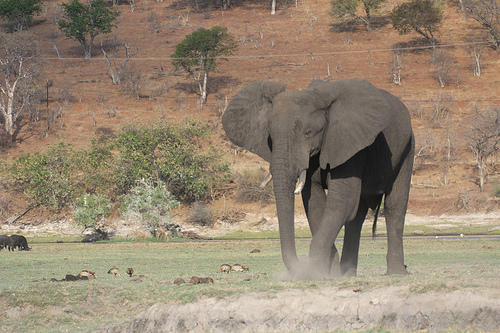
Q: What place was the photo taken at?
A: It was taken at the field.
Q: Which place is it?
A: It is a field.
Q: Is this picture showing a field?
A: Yes, it is showing a field.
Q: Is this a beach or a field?
A: It is a field.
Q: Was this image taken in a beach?
A: No, the picture was taken in a field.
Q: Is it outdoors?
A: Yes, it is outdoors.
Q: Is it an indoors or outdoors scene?
A: It is outdoors.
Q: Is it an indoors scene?
A: No, it is outdoors.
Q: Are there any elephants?
A: Yes, there is an elephant.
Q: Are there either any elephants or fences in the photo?
A: Yes, there is an elephant.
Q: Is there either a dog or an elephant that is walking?
A: Yes, the elephant is walking.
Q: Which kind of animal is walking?
A: The animal is an elephant.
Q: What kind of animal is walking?
A: The animal is an elephant.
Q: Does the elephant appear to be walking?
A: Yes, the elephant is walking.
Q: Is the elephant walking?
A: Yes, the elephant is walking.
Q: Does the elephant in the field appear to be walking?
A: Yes, the elephant is walking.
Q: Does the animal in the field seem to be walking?
A: Yes, the elephant is walking.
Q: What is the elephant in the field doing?
A: The elephant is walking.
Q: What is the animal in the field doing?
A: The elephant is walking.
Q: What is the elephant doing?
A: The elephant is walking.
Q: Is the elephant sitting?
A: No, the elephant is walking.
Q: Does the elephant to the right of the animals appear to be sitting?
A: No, the elephant is walking.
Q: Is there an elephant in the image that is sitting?
A: No, there is an elephant but it is walking.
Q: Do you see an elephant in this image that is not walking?
A: No, there is an elephant but it is walking.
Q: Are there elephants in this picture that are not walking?
A: No, there is an elephant but it is walking.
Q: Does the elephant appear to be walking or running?
A: The elephant is walking.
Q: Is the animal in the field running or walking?
A: The elephant is walking.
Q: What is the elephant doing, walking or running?
A: The elephant is walking.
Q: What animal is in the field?
A: The elephant is in the field.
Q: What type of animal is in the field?
A: The animal is an elephant.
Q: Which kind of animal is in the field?
A: The animal is an elephant.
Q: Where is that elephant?
A: The elephant is in the field.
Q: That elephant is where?
A: The elephant is in the field.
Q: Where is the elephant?
A: The elephant is in the field.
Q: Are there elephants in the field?
A: Yes, there is an elephant in the field.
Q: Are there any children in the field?
A: No, there is an elephant in the field.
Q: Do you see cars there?
A: No, there are no cars.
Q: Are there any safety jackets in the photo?
A: No, there are no safety jackets.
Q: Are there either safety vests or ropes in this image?
A: No, there are no safety vests or ropes.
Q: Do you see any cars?
A: No, there are no cars.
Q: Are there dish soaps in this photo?
A: No, there are no dish soaps.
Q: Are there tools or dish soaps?
A: No, there are no dish soaps or tools.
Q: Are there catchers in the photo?
A: No, there are no catchers.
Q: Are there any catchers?
A: No, there are no catchers.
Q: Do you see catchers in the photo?
A: No, there are no catchers.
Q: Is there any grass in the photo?
A: Yes, there is grass.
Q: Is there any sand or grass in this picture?
A: Yes, there is grass.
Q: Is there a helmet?
A: No, there are no helmets.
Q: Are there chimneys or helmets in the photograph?
A: No, there are no helmets or chimneys.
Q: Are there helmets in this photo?
A: No, there are no helmets.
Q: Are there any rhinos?
A: Yes, there are rhinos.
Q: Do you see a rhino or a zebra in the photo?
A: Yes, there are rhinos.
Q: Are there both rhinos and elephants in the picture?
A: Yes, there are both rhinos and an elephant.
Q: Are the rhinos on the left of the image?
A: Yes, the rhinos are on the left of the image.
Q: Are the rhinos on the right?
A: No, the rhinos are on the left of the image.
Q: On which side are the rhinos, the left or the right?
A: The rhinos are on the left of the image.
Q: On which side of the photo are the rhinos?
A: The rhinos are on the left of the image.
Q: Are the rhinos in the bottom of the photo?
A: Yes, the rhinos are in the bottom of the image.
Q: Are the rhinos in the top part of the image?
A: No, the rhinos are in the bottom of the image.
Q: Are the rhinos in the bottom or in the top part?
A: The rhinos are in the bottom of the image.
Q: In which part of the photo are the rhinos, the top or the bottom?
A: The rhinos are in the bottom of the image.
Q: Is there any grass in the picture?
A: Yes, there is grass.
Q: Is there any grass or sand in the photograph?
A: Yes, there is grass.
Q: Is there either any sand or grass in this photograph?
A: Yes, there is grass.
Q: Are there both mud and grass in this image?
A: No, there is grass but no mud.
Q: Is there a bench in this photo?
A: No, there are no benches.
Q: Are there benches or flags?
A: No, there are no benches or flags.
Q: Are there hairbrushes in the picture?
A: No, there are no hairbrushes.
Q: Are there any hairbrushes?
A: No, there are no hairbrushes.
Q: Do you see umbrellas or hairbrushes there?
A: No, there are no hairbrushes or umbrellas.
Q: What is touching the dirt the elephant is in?
A: The trunk is touching the dirt.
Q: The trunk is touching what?
A: The trunk is touching the dirt.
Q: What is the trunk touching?
A: The trunk is touching the dirt.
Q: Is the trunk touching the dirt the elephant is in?
A: Yes, the trunk is touching the dirt.